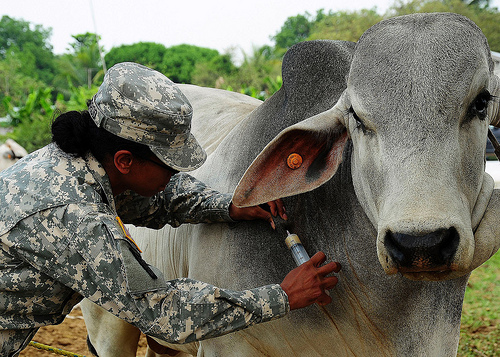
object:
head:
[231, 12, 498, 282]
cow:
[79, 11, 498, 357]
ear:
[231, 108, 348, 208]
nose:
[383, 227, 460, 263]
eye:
[473, 91, 488, 113]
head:
[51, 62, 193, 198]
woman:
[1, 62, 343, 356]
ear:
[114, 150, 132, 175]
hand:
[282, 251, 342, 311]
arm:
[70, 219, 285, 345]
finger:
[318, 262, 342, 276]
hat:
[90, 61, 208, 172]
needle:
[284, 230, 329, 297]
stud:
[286, 153, 303, 170]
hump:
[281, 39, 355, 98]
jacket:
[0, 140, 291, 357]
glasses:
[141, 155, 180, 175]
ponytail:
[52, 110, 92, 154]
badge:
[116, 217, 143, 253]